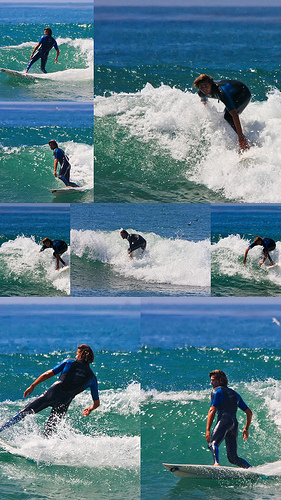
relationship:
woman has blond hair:
[192, 73, 251, 149] [191, 73, 215, 86]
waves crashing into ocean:
[65, 37, 91, 94] [5, 68, 188, 130]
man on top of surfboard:
[120, 230, 148, 257] [189, 112, 266, 176]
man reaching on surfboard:
[188, 72, 254, 154] [161, 461, 279, 478]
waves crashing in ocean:
[140, 385, 213, 412] [139, 297, 280, 499]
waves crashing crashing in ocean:
[70, 369, 140, 480] [1, 306, 134, 491]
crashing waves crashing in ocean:
[163, 234, 205, 289] [70, 203, 210, 296]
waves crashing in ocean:
[135, 104, 277, 199] [93, 0, 279, 202]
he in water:
[206, 369, 252, 467] [93, 0, 280, 202]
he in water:
[48, 139, 80, 188] [93, 0, 280, 202]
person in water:
[26, 20, 63, 74] [93, 0, 280, 202]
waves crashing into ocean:
[102, 71, 209, 164] [5, 302, 276, 490]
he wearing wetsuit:
[177, 356, 254, 470] [201, 383, 251, 468]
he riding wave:
[26, 131, 88, 197] [3, 384, 158, 475]